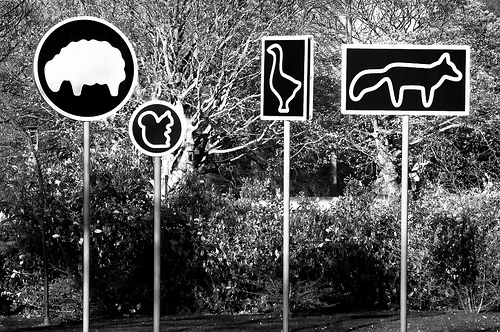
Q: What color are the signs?
A: Black and white.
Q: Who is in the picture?
A: There are no people in the image.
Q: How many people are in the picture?
A: One.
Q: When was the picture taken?
A: During the day.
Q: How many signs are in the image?
A: Four.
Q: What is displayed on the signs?
A: Images of animals.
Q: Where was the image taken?
A: At a park.